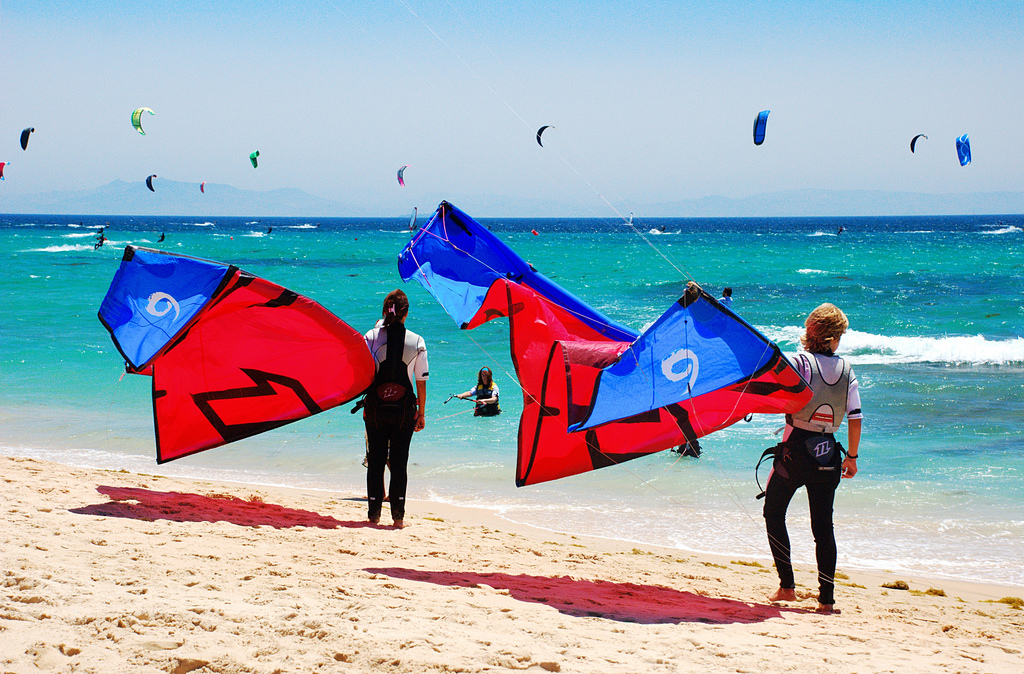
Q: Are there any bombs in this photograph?
A: No, there are no bombs.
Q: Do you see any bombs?
A: No, there are no bombs.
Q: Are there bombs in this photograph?
A: No, there are no bombs.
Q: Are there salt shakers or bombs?
A: No, there are no bombs or salt shakers.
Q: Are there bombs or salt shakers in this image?
A: No, there are no bombs or salt shakers.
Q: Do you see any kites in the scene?
A: Yes, there is a kite.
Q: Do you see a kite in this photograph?
A: Yes, there is a kite.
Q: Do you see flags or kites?
A: Yes, there is a kite.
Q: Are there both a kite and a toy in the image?
A: No, there is a kite but no toys.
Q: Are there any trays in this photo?
A: No, there are no trays.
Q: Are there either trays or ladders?
A: No, there are no trays or ladders.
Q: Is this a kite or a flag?
A: This is a kite.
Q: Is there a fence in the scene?
A: No, there are no fences.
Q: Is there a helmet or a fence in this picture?
A: No, there are no fences or helmets.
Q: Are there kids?
A: No, there are no kids.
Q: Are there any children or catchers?
A: No, there are no children or catchers.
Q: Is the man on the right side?
A: Yes, the man is on the right of the image.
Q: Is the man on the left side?
A: No, the man is on the right of the image.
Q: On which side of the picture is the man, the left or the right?
A: The man is on the right of the image.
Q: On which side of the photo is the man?
A: The man is on the right of the image.